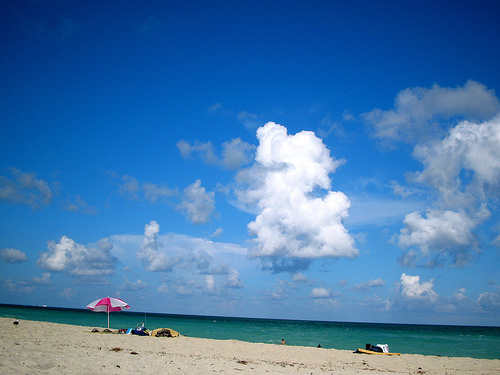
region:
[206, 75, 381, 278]
large puffy white cloud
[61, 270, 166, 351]
red and white open umbrella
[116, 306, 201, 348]
personal belongings left on sand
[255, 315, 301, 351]
head and torso of person near the water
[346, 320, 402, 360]
black, white and yellow belongings near water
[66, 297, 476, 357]
ocean surface a dark green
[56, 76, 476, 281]
blue sky with many clouds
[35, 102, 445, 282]
sandy beach with natural debris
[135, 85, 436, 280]
whitest cloud in the sky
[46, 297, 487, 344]
thick and dark line at the horizon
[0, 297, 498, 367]
The ocean water is calm.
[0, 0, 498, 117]
The sky is blue.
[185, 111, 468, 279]
The sky contains clouds.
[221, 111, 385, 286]
The clouds are puffy and white.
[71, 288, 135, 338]
The beach umbrella is pink and white.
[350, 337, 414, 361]
People are lying on the beach.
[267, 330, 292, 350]
A person is in the water.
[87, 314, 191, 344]
Blankets and belongings are on the beach.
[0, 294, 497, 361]
The water is green.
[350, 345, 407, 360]
The blanket is yellow.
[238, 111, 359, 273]
Clouds in the sky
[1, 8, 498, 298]
Sky is blue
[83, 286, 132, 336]
Parasol is red and white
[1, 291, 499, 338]
Water of sea is green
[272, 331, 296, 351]
Person in the sea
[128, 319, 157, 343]
Person taking a bath sun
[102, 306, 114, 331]
Stick of parasol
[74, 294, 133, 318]
Canopy of parasol is red and white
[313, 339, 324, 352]
Person in the water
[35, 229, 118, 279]
Clouds in the sky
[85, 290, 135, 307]
One umbrella is seen.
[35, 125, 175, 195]
Sky is blue color.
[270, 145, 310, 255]
Clouds are white color.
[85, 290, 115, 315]
Umbrella is red and white color.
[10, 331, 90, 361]
Sand is brown color.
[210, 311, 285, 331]
Water is blue color.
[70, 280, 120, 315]
Umbrella is in sand.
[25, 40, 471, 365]
Day time picture.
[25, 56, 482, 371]
Picture is taken in beach.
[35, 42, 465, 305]
Sky is with some clouds.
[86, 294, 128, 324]
pink and white umbrella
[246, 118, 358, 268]
large white cloud in center of picture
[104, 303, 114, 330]
pole of the umbrella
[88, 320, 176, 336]
personal belongings on the beach near umbrella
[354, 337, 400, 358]
personal belongings on right side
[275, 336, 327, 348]
two people in the ocean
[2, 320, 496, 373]
sandy beach near the ocean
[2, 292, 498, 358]
ocean waters beyond the beach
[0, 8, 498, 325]
bright blue sky with clouds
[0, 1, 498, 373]
a summer beach scene